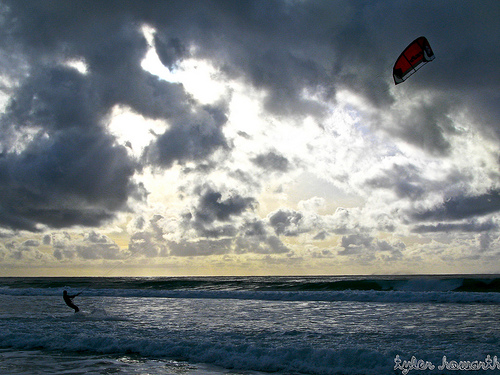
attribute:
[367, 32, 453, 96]
kite — large, close, big, flying, high, red, black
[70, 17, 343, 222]
sky — high, overcast, cloudy, dark, white, blue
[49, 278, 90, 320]
man — wet, standing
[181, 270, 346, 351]
water — below, blue, wet, smooth, wavy